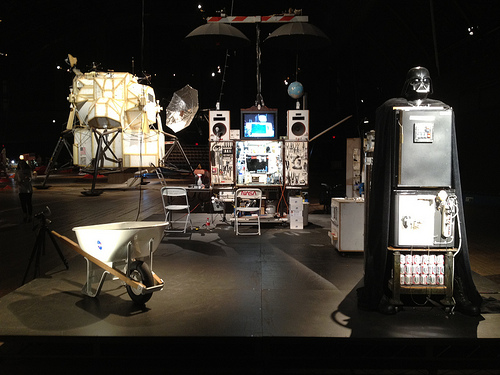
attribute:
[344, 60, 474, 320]
robot — made, here, metal, large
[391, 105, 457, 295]
boxes — electronics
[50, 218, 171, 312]
wheelbarrow — white, metal, wood, here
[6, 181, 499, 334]
floor — dark, here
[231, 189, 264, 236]
chair — open, folding, white, gray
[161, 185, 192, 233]
chair — open, folding, plain, white, here, gray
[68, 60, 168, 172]
structure — composed, taped, yellow, white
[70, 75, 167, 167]
panels — hite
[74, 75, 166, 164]
strips — wood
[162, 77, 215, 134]
umbrella — reflective, silver, photographer's, here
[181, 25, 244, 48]
umbrella — black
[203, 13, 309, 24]
bar — orange, white, long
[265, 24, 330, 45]
umbrella — black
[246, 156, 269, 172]
opening — rectangular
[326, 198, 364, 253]
cabinet — white, trimmed, gray, file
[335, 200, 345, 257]
wood — light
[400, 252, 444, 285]
cans — stacked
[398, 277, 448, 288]
row — cans, stacked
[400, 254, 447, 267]
row — cans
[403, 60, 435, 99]
head — darth vadar, character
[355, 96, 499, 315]
cape — darth vadar, black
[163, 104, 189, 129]
light — reflecting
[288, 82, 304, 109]
globe — earth, here, round, model, blue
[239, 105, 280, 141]
television — here, on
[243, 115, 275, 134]
screen — metallic, flash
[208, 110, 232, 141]
speaker — white, stereo, black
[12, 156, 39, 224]
lady — here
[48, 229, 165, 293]
handles — wooden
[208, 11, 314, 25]
sign — red, white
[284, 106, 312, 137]
speaker — black, white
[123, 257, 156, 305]
tire — black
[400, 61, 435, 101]
character — star wars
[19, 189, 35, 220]
pants — black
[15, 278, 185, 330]
shadow — wheelbarrow